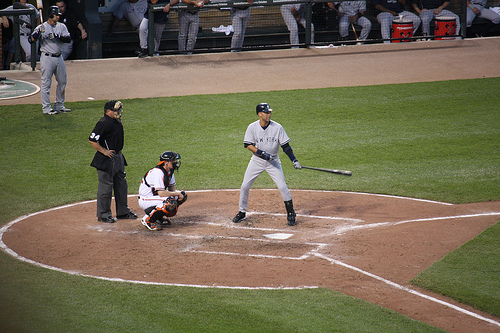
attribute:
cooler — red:
[387, 12, 415, 44]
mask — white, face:
[103, 95, 126, 120]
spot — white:
[86, 95, 94, 101]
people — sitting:
[0, 0, 500, 60]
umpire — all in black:
[86, 91, 141, 233]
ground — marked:
[382, 133, 418, 177]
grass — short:
[0, 79, 497, 329]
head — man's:
[257, 97, 281, 131]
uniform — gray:
[247, 124, 283, 150]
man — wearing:
[236, 95, 351, 252]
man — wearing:
[130, 137, 200, 239]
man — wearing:
[72, 87, 142, 245]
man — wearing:
[22, 2, 79, 127]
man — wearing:
[140, 2, 175, 56]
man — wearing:
[168, 2, 207, 64]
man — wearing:
[329, 0, 379, 44]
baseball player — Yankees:
[246, 95, 291, 143]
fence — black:
[153, 4, 498, 49]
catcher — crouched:
[136, 137, 202, 233]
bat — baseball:
[291, 164, 351, 179]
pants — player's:
[233, 150, 293, 212]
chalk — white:
[2, 180, 497, 324]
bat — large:
[296, 162, 357, 180]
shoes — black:
[229, 209, 298, 227]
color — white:
[392, 192, 456, 208]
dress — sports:
[233, 119, 304, 210]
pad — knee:
[158, 197, 180, 217]